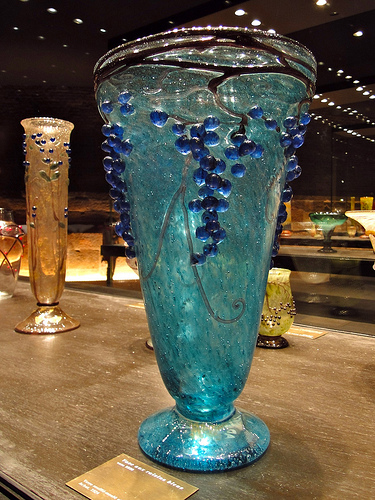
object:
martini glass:
[344, 208, 374, 269]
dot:
[189, 253, 205, 269]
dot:
[216, 198, 227, 212]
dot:
[249, 105, 265, 118]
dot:
[149, 109, 168, 127]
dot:
[281, 188, 289, 201]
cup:
[92, 27, 316, 471]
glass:
[254, 264, 295, 350]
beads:
[277, 322, 280, 327]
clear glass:
[0, 220, 25, 303]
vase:
[91, 26, 316, 475]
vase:
[12, 116, 78, 337]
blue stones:
[231, 163, 246, 178]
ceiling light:
[350, 28, 365, 37]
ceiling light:
[314, 0, 328, 8]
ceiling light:
[232, 7, 248, 16]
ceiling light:
[246, 18, 262, 29]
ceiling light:
[266, 27, 277, 33]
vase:
[307, 211, 349, 251]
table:
[0, 281, 375, 498]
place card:
[64, 452, 194, 498]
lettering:
[115, 455, 184, 490]